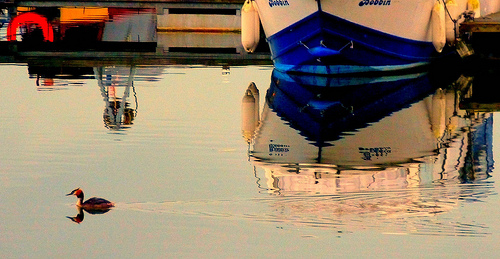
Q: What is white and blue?
A: Boat.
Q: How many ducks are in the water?
A: One.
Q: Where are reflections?
A: On the water.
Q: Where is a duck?
A: In the water.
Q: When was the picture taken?
A: Daytime.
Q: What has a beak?
A: The duck.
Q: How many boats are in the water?
A: Only one.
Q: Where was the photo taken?
A: Marina.